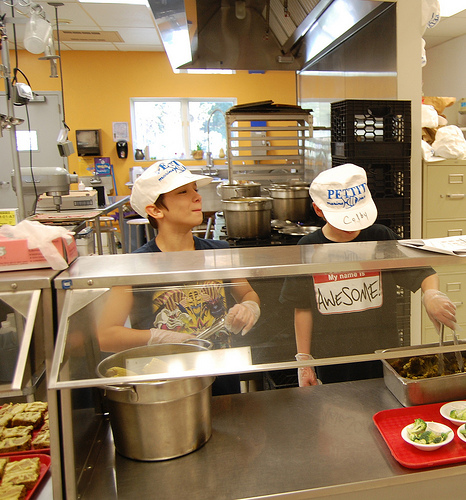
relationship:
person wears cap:
[98, 158, 262, 397] [124, 155, 211, 217]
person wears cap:
[98, 158, 262, 397] [288, 151, 393, 234]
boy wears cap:
[279, 163, 457, 388] [117, 150, 218, 221]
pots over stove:
[216, 178, 313, 243] [203, 210, 322, 249]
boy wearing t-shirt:
[279, 163, 457, 388] [278, 223, 437, 385]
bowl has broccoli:
[398, 416, 456, 454] [408, 420, 452, 449]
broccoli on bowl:
[409, 417, 444, 444] [398, 413, 455, 456]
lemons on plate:
[405, 414, 451, 447] [397, 416, 457, 454]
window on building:
[113, 51, 270, 212] [63, 22, 375, 244]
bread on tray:
[5, 406, 49, 445] [2, 401, 51, 452]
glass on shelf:
[61, 264, 464, 380] [46, 259, 464, 388]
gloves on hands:
[146, 303, 270, 352] [146, 307, 272, 346]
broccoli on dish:
[409, 417, 444, 444] [398, 419, 453, 454]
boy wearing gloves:
[279, 163, 458, 390] [419, 287, 460, 333]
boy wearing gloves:
[279, 163, 458, 390] [291, 352, 323, 385]